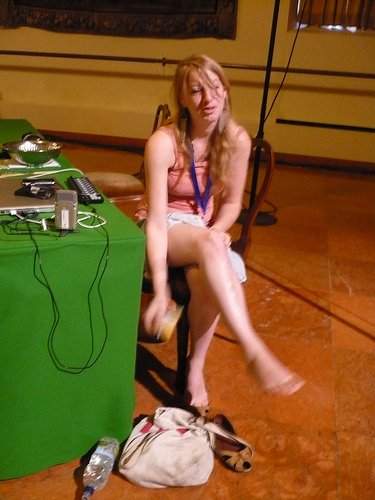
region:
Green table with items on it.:
[12, 244, 35, 383]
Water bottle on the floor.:
[76, 434, 121, 498]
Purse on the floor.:
[136, 405, 211, 485]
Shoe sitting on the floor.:
[208, 414, 257, 471]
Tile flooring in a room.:
[316, 330, 369, 432]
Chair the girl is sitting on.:
[244, 137, 278, 240]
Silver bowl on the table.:
[6, 133, 67, 176]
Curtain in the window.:
[307, 1, 368, 29]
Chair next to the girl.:
[92, 166, 135, 201]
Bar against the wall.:
[46, 47, 154, 86]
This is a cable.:
[20, 229, 119, 376]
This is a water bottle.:
[67, 426, 127, 496]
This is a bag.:
[112, 394, 224, 498]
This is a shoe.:
[203, 406, 260, 481]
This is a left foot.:
[161, 356, 223, 417]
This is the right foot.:
[226, 326, 320, 403]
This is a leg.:
[200, 244, 314, 399]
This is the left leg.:
[181, 288, 237, 424]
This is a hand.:
[147, 280, 194, 337]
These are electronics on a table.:
[16, 177, 118, 234]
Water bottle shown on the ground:
[78, 433, 123, 498]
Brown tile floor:
[0, 138, 373, 499]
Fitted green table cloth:
[0, 116, 148, 481]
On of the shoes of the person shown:
[205, 406, 258, 472]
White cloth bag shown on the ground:
[115, 402, 233, 490]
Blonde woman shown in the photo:
[133, 45, 309, 414]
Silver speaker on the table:
[51, 185, 82, 236]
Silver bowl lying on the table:
[4, 135, 66, 166]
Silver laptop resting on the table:
[1, 173, 70, 218]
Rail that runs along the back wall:
[1, 44, 373, 85]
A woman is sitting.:
[129, 43, 311, 418]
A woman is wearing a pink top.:
[128, 108, 248, 232]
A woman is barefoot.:
[160, 330, 304, 411]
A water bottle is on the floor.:
[71, 427, 119, 496]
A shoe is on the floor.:
[198, 405, 252, 476]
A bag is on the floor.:
[109, 394, 221, 488]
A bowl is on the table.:
[0, 128, 69, 173]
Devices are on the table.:
[11, 169, 109, 237]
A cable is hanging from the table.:
[15, 199, 116, 375]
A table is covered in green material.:
[0, 99, 155, 484]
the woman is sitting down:
[141, 60, 303, 413]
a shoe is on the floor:
[208, 413, 258, 470]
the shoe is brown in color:
[203, 413, 257, 475]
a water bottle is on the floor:
[75, 434, 121, 497]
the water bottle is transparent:
[81, 435, 117, 496]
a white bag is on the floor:
[117, 403, 226, 487]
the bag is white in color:
[124, 405, 212, 491]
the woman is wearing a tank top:
[137, 126, 230, 224]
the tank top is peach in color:
[136, 124, 218, 217]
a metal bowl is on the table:
[1, 136, 63, 166]